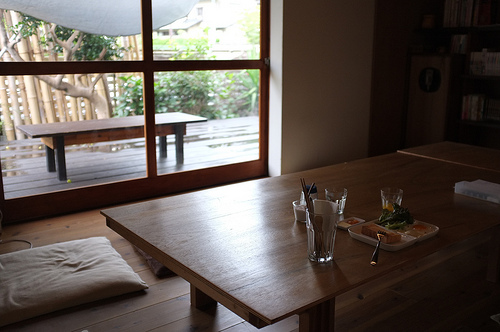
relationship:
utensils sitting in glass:
[305, 190, 329, 261] [300, 204, 348, 269]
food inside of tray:
[377, 213, 415, 237] [351, 206, 420, 256]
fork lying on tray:
[365, 233, 390, 266] [351, 206, 420, 256]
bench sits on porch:
[32, 107, 194, 176] [12, 110, 256, 193]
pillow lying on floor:
[1, 223, 112, 311] [5, 228, 289, 331]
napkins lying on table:
[448, 172, 499, 220] [89, 135, 495, 330]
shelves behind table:
[404, 6, 498, 152] [89, 135, 495, 330]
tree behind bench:
[21, 32, 247, 114] [32, 107, 194, 176]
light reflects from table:
[200, 188, 273, 275] [89, 135, 495, 330]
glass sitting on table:
[300, 204, 348, 269] [89, 135, 495, 330]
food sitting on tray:
[377, 213, 415, 237] [343, 206, 443, 255]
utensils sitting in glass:
[300, 177, 314, 214] [300, 204, 348, 269]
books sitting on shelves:
[452, 77, 497, 135] [404, 6, 498, 152]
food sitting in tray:
[377, 213, 415, 237] [351, 206, 420, 256]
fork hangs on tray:
[365, 233, 390, 266] [351, 206, 420, 256]